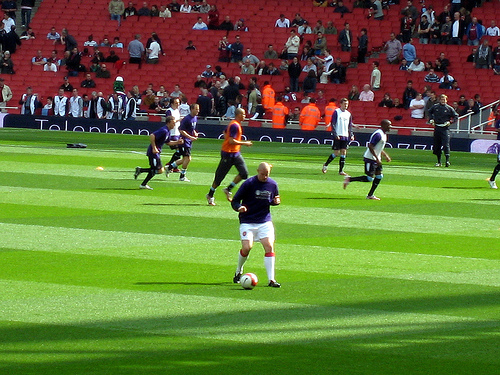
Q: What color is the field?
A: Green.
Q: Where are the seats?
A: In the stand.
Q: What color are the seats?
A: Red.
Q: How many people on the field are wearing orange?
A: 1.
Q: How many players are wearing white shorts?
A: 1.